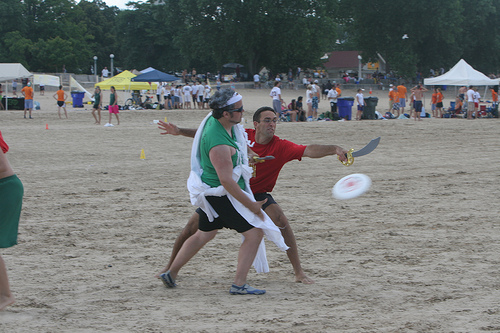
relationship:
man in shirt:
[158, 87, 268, 297] [199, 115, 247, 193]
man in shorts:
[158, 87, 268, 297] [196, 193, 255, 232]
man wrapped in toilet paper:
[158, 87, 268, 297] [187, 111, 290, 251]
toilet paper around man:
[187, 111, 290, 251] [158, 87, 268, 297]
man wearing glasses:
[158, 87, 268, 297] [227, 106, 244, 114]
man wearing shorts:
[158, 87, 268, 297] [196, 193, 255, 232]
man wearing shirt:
[158, 87, 268, 297] [199, 115, 247, 193]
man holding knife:
[246, 106, 348, 287] [343, 136, 383, 168]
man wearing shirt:
[246, 106, 348, 287] [245, 126, 308, 194]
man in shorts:
[246, 106, 348, 287] [252, 190, 277, 210]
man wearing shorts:
[246, 106, 348, 287] [252, 190, 277, 210]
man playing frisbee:
[246, 106, 348, 287] [329, 172, 371, 202]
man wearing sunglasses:
[158, 87, 268, 297] [227, 106, 244, 114]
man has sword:
[246, 106, 348, 287] [343, 136, 383, 168]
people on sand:
[270, 78, 498, 128] [1, 109, 496, 328]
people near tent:
[270, 78, 498, 128] [422, 57, 498, 101]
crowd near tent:
[386, 79, 500, 119] [422, 57, 498, 101]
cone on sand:
[135, 146, 147, 162] [1, 109, 496, 328]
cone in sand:
[42, 121, 50, 132] [1, 109, 496, 328]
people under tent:
[428, 86, 498, 117] [422, 57, 498, 101]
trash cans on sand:
[334, 94, 378, 123] [1, 109, 496, 328]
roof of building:
[320, 47, 388, 73] [321, 49, 386, 83]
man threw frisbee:
[158, 87, 268, 297] [329, 172, 371, 202]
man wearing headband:
[158, 87, 268, 297] [213, 92, 245, 109]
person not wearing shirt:
[408, 83, 429, 122] [410, 84, 424, 101]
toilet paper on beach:
[158, 83, 272, 280] [1, 109, 496, 328]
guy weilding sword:
[246, 106, 348, 287] [343, 136, 383, 168]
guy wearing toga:
[158, 87, 268, 297] [187, 111, 290, 251]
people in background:
[270, 78, 498, 128] [1, 1, 497, 121]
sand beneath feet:
[1, 109, 496, 328] [156, 262, 319, 299]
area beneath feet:
[0, 285, 500, 332] [156, 262, 319, 299]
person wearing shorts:
[1, 128, 24, 313] [2, 174, 25, 250]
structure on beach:
[1, 60, 35, 113] [1, 109, 496, 328]